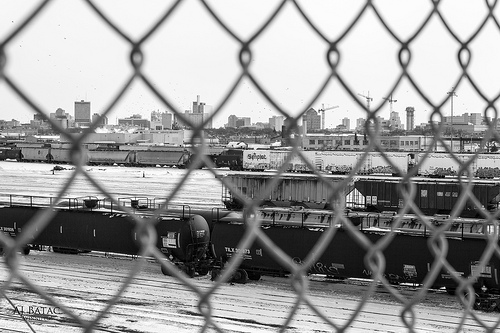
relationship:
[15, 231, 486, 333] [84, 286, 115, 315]
tracks are covered in snow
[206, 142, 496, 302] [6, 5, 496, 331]
trains behind fence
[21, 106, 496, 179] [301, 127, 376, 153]
building with windows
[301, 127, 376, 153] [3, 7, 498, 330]
windows in distance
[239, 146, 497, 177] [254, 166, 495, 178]
train have graffiti